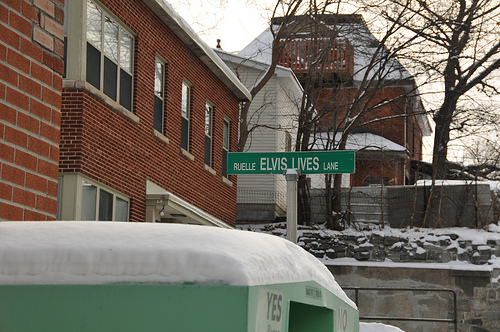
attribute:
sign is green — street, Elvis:
[223, 150, 370, 186]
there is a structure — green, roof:
[0, 222, 360, 332]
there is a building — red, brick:
[1, 1, 251, 231]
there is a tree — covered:
[239, 1, 420, 228]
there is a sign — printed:
[255, 287, 294, 331]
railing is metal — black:
[343, 279, 470, 332]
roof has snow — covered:
[239, 10, 411, 92]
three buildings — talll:
[1, 2, 436, 233]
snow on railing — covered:
[299, 187, 391, 230]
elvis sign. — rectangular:
[227, 152, 355, 175]